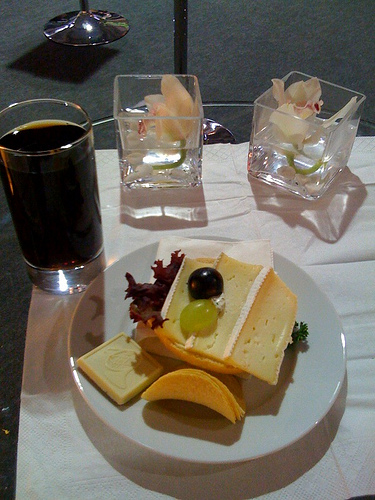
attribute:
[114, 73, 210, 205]
glass — square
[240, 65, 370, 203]
glass — square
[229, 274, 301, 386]
slice — cheese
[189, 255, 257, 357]
slice — cheese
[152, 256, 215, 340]
slice — cheese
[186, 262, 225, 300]
grape — dark, purple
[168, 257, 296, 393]
cheese — sliced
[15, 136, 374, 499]
napkin — white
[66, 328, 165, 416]
chocolate square — white chocolate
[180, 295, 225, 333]
grape — green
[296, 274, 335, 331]
plate — artistic, snack plate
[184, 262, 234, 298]
grape — red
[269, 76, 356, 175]
orchid — white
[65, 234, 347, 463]
plate — white, round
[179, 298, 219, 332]
grape — cut in half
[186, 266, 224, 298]
grape — cut in half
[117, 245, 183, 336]
lettuce — red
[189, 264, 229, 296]
grape — red